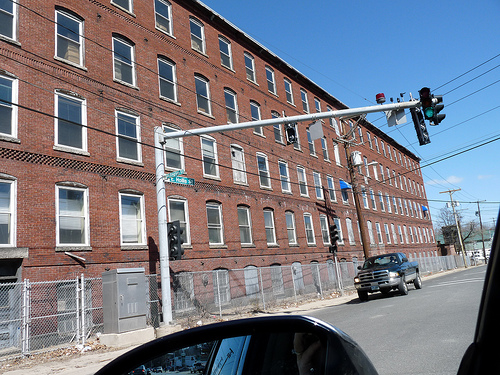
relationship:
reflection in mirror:
[128, 330, 330, 374] [91, 307, 380, 372]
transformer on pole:
[347, 144, 368, 168] [345, 163, 372, 264]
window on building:
[255, 150, 275, 190] [2, 2, 442, 304]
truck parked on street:
[352, 251, 424, 303] [294, 260, 485, 374]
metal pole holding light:
[141, 114, 178, 338] [412, 70, 452, 130]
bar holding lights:
[154, 100, 419, 137] [404, 104, 438, 146]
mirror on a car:
[97, 312, 380, 374] [91, 200, 499, 374]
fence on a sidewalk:
[1, 241, 476, 358] [14, 257, 474, 374]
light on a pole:
[394, 83, 465, 131] [138, 97, 336, 165]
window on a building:
[218, 106, 442, 216] [0, 1, 440, 356]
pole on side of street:
[153, 96, 419, 326] [318, 250, 487, 374]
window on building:
[53, 7, 93, 68] [2, 2, 442, 304]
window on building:
[190, 74, 212, 113] [2, 2, 442, 304]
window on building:
[112, 31, 140, 89] [2, 2, 442, 304]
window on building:
[52, 90, 90, 152] [2, 2, 442, 304]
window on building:
[114, 104, 146, 166] [2, 2, 442, 304]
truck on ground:
[352, 251, 421, 301] [337, 281, 479, 337]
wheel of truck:
[412, 271, 422, 289] [352, 251, 424, 303]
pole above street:
[153, 96, 419, 326] [303, 265, 487, 373]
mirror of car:
[124, 325, 359, 374] [91, 200, 499, 374]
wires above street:
[435, 52, 499, 156] [116, 257, 486, 373]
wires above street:
[355, 114, 422, 178] [116, 257, 486, 373]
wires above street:
[421, 162, 440, 193] [116, 257, 486, 373]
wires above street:
[482, 202, 497, 222] [116, 257, 486, 373]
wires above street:
[427, 197, 442, 222] [116, 257, 486, 373]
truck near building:
[352, 251, 421, 301] [0, 1, 440, 356]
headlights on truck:
[353, 268, 405, 291] [351, 241, 429, 311]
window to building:
[119, 189, 147, 247] [0, 1, 440, 356]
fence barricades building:
[1, 253, 478, 357] [0, 1, 440, 356]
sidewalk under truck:
[14, 260, 491, 374] [336, 230, 429, 296]